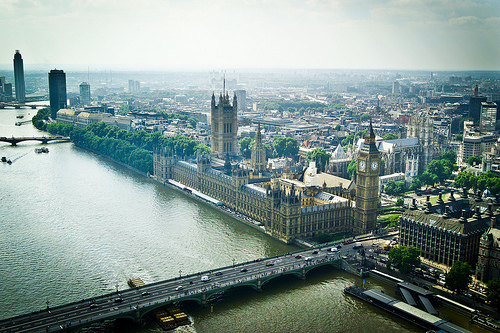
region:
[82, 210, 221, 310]
the water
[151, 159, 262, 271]
the water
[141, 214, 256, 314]
the water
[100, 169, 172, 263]
the water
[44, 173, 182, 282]
the water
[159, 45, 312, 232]
a tall building with points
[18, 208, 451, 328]
a bridge over water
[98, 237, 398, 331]
a bridge with vehicles on it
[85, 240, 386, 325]
vehicles on a bridge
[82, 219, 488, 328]
vehicles driving over the water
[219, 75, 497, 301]
buildings along the water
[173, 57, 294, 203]
a tall building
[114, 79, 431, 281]
a big building along the water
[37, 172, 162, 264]
a body of water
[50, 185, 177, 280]
a calm body of water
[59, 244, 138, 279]
the water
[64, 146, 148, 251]
the water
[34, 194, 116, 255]
the water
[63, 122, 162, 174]
a row of green trees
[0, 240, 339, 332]
a bridge over the water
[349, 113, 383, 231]
a large clock tower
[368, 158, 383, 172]
a white clock face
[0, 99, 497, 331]
a river next to the building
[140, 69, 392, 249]
a large building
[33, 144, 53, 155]
a boat in the water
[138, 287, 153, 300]
a car on the bridge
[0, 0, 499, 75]
a gray sky overhead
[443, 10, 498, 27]
a cloud in the sky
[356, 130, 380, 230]
the big ben clock tower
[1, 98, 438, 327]
the river next to all the buildings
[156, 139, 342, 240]
a large castle type building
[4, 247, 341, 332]
a bridge covering the river for the cars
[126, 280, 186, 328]
a boat below the bridge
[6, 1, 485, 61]
the sky with some white clouds above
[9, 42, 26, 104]
a tall building standing by itself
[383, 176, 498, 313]
another building next to the bridge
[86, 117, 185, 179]
a line of trees by the river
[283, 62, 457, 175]
the city with a lot of buildings